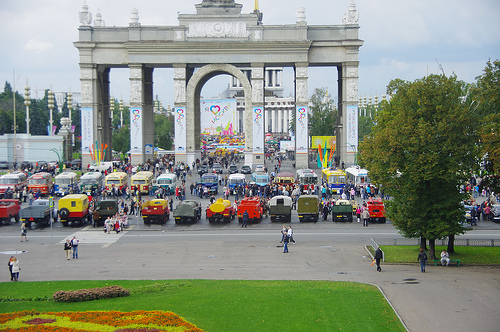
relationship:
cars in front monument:
[0, 162, 387, 223] [70, 2, 358, 192]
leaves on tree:
[393, 112, 461, 195] [361, 71, 472, 246]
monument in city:
[74, 5, 363, 174] [7, 3, 498, 329]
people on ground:
[5, 138, 375, 210] [10, 223, 477, 322]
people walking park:
[91, 139, 299, 199] [11, 150, 484, 330]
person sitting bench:
[437, 245, 452, 267] [426, 256, 463, 268]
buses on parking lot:
[0, 168, 182, 194] [0, 163, 497, 228]